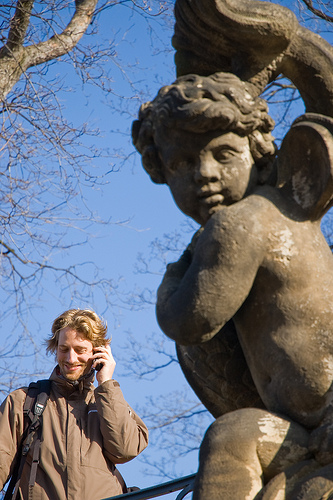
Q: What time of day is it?
A: Day time.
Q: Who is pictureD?
A: Man.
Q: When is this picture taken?
A: Fall.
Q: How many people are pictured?
A: One.